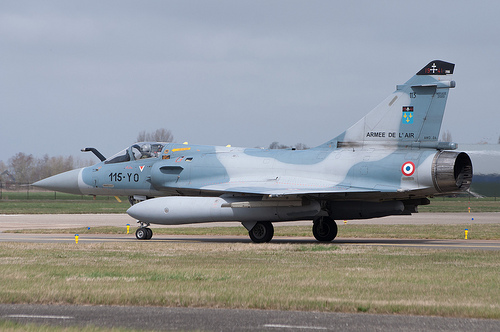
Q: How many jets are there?
A: 1.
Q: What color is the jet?
A: Gray.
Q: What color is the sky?
A: Blue.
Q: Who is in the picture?
A: No one.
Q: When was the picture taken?
A: In the day time.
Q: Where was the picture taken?
A: On a tarmat.